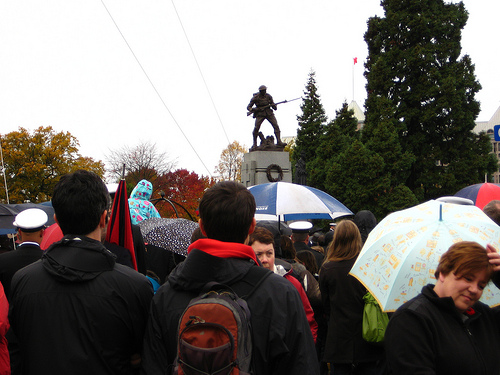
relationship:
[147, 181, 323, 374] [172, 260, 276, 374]
man wearing backpack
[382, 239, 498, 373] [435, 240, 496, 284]
lady touching hair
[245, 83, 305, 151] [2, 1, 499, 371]
statue inside of photo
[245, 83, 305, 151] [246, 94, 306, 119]
statue holding gun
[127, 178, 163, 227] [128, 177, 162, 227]
kid wearing raincoat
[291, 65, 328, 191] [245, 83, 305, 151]
tree next to statue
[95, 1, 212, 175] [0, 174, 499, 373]
wire above crowd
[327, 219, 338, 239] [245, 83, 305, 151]
person in front of statue